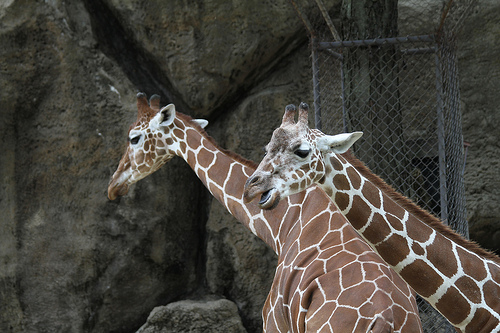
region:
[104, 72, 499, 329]
giraffes standing together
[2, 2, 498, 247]
the walls is made of rock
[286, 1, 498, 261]
the fence is gray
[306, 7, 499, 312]
a tree trunk is inside the fence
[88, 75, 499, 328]
the giraffes are brown and white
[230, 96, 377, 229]
the giraffe has it's mouth open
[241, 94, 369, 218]
the giraffe has a white ear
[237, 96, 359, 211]
the giraffe has an eye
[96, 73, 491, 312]
the giraffes have long necks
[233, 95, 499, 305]
the giraffe has hair on its neck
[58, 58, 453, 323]
two giraffes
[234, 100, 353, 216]
a giraffe with its mouth open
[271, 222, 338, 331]
pattern on a giraffe's body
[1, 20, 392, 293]
large rock enclosure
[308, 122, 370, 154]
a giraffe's ear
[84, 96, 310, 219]
a giraffe with its neck down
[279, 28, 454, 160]
a fence around a tree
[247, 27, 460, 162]
a tall chain link fence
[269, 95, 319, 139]
two horns on a giraffe's head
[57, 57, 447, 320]
two giraffe's standing next to each other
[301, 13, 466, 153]
chain link fencing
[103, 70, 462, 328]
two giraffes in rock pen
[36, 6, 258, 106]
large rocks behind giraffes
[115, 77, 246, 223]
giraffes head on the left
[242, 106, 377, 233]
giraffes head on the right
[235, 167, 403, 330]
first giraffes back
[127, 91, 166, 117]
horns on giraffe on left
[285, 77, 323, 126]
horns of giraffe on right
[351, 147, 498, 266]
giraffe on the rights mane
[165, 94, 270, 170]
giraffe on the left's mane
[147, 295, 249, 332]
large gray stone in enclosure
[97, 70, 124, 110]
white spot on stone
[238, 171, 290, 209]
open mouth on giraffe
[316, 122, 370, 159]
white ears on giraffe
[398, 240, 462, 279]
solid white line on giraffe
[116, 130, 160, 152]
doe black eyes on girafe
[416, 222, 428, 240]
beautiful brown section on giraffe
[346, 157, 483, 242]
long brown comb on giraffe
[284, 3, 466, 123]
large chain link silver fence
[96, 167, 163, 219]
brown mouth on giraffe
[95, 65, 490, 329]
two giraffes in a zoo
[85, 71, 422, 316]
pair of giraffes standing together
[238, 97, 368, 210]
giraffe with open mouth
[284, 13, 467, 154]
fence surrounding tree for safety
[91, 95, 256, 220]
giraffe with ears back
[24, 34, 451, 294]
giraffes at a zoo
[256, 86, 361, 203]
giraffe with white ears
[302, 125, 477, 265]
mane on giraffe's neck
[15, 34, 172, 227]
stone wall in giraffe enclosure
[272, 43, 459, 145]
chain link fence around tree